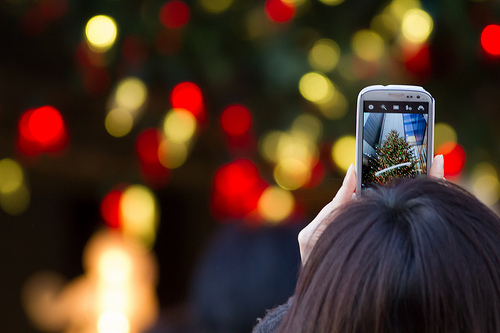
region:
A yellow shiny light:
[80, 13, 121, 48]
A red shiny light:
[27, 106, 67, 138]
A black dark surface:
[4, 8, 69, 86]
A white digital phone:
[344, 83, 454, 165]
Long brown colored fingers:
[342, 159, 357, 195]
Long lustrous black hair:
[346, 200, 495, 322]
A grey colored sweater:
[254, 297, 277, 332]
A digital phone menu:
[364, 100, 429, 110]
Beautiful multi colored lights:
[103, 65, 299, 217]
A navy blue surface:
[208, 236, 292, 297]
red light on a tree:
[10, 100, 78, 169]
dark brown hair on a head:
[339, 247, 416, 300]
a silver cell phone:
[357, 76, 430, 185]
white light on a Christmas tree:
[81, 13, 126, 50]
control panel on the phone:
[366, 97, 427, 117]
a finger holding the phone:
[338, 160, 360, 200]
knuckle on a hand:
[294, 227, 304, 247]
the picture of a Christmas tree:
[357, 127, 423, 182]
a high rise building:
[362, 115, 421, 127]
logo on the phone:
[384, 87, 411, 97]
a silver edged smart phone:
[354, 84, 434, 201]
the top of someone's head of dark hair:
[280, 173, 499, 331]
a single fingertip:
[424, 153, 444, 180]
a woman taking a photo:
[252, 83, 498, 330]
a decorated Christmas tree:
[362, 128, 423, 193]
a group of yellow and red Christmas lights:
[126, 80, 208, 187]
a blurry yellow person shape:
[18, 228, 162, 332]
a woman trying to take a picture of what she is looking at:
[250, 82, 498, 332]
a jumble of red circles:
[10, 104, 70, 163]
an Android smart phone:
[352, 83, 434, 202]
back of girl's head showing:
[209, 111, 464, 321]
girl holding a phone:
[240, 47, 450, 227]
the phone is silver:
[319, 47, 476, 214]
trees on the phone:
[371, 118, 428, 205]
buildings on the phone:
[367, 112, 439, 156]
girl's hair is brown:
[281, 163, 453, 308]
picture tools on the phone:
[364, 96, 433, 117]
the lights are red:
[18, 88, 80, 157]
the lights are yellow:
[97, 70, 168, 157]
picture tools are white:
[361, 100, 433, 115]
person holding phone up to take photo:
[244, 75, 498, 332]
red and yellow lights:
[8, 6, 490, 273]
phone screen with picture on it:
[366, 107, 426, 189]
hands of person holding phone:
[285, 155, 464, 255]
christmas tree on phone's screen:
[368, 126, 421, 184]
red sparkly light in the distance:
[25, 5, 486, 212]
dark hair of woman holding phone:
[292, 180, 498, 329]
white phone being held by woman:
[350, 77, 443, 200]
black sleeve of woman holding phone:
[250, 300, 299, 332]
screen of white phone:
[362, 103, 425, 189]